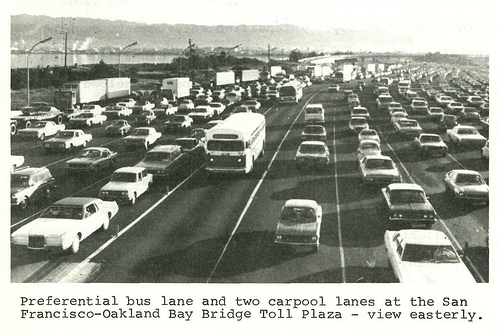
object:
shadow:
[134, 231, 272, 275]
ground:
[0, 54, 493, 299]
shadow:
[271, 178, 372, 202]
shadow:
[319, 203, 382, 247]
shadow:
[255, 159, 294, 177]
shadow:
[385, 141, 418, 166]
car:
[271, 199, 323, 249]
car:
[295, 140, 330, 168]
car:
[356, 154, 399, 182]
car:
[413, 131, 447, 158]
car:
[380, 181, 437, 227]